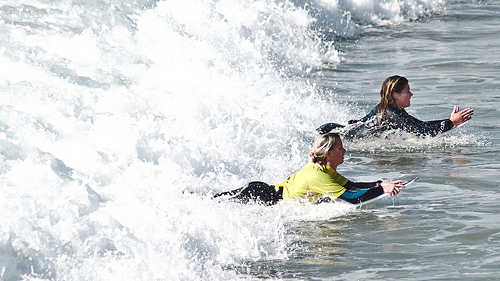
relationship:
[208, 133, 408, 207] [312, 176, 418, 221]
woman laying on surfboard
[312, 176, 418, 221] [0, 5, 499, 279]
surfboard in water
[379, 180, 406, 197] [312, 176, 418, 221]
hand on surfboard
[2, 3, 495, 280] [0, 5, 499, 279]
white froth on top of water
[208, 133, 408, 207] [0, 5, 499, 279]
woman in water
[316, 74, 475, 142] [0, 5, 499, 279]
girl in water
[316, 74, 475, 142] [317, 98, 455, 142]
girl wearing wet suit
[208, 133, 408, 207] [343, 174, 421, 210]
woman on surfboard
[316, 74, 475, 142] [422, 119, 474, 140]
girl on board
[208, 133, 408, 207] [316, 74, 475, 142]
woman next to girl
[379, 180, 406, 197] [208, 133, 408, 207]
hand on woman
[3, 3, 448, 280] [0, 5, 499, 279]
wave in water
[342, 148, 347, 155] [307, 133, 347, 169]
nose on head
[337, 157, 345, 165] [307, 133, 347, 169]
chin on head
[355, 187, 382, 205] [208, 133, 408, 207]
forearm on woman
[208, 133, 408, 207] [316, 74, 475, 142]
woman swimming next to girl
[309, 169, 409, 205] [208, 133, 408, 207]
arm of woman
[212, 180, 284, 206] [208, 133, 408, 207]
pants on woman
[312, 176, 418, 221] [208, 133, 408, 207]
surfboard under woman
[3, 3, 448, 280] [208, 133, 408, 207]
wave behind woman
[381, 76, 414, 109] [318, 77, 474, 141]
head of woman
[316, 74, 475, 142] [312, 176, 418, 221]
girl on surfboard